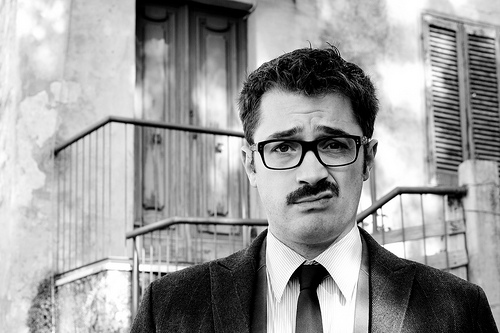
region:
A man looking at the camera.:
[133, 46, 499, 331]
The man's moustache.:
[285, 181, 341, 205]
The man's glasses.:
[248, 135, 370, 170]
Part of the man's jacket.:
[173, 280, 199, 327]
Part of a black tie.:
[290, 263, 328, 332]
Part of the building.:
[42, 45, 73, 78]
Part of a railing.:
[67, 133, 124, 258]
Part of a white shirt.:
[325, 306, 345, 331]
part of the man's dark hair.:
[294, 58, 337, 79]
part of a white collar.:
[271, 251, 284, 274]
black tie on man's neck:
[296, 262, 323, 329]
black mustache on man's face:
[281, 183, 343, 198]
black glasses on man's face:
[262, 136, 362, 173]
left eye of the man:
[324, 138, 349, 158]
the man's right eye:
[275, 140, 296, 161]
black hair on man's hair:
[245, 44, 377, 96]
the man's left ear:
[365, 136, 378, 184]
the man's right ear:
[242, 140, 259, 190]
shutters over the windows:
[427, 17, 498, 155]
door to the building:
[133, 2, 240, 227]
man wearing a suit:
[97, 35, 499, 330]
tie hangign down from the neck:
[282, 253, 332, 332]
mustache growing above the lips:
[279, 181, 349, 204]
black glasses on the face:
[242, 131, 376, 173]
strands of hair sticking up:
[304, 36, 315, 53]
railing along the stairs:
[351, 163, 494, 299]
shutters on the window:
[414, 5, 499, 212]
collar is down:
[250, 231, 375, 302]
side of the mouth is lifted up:
[292, 189, 339, 216]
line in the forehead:
[290, 103, 327, 118]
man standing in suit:
[127, 39, 498, 331]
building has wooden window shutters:
[418, 8, 498, 192]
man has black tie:
[294, 260, 326, 330]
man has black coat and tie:
[128, 218, 498, 332]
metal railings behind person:
[55, 115, 467, 315]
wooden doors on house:
[133, 0, 255, 271]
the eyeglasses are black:
[240, 132, 372, 170]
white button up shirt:
[258, 230, 357, 331]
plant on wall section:
[23, 269, 66, 328]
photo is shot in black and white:
[1, 1, 499, 331]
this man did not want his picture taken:
[47, 22, 499, 260]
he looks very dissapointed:
[188, 31, 408, 299]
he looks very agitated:
[110, 42, 461, 317]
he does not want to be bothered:
[173, 43, 434, 304]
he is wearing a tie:
[248, 236, 375, 331]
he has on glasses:
[252, 115, 377, 190]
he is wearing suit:
[134, 234, 459, 331]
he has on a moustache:
[268, 173, 346, 215]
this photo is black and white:
[45, 19, 485, 304]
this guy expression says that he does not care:
[125, 42, 493, 317]